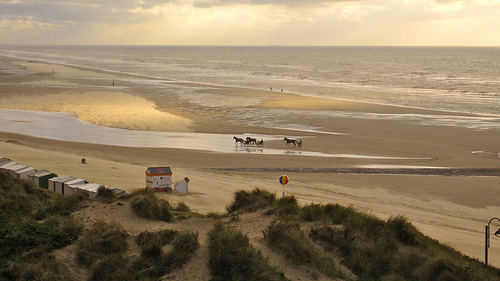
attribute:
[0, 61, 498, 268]
beach — wet, beige, golden, dry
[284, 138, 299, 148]
horse — walking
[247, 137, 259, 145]
horse — walking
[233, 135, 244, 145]
horse — walking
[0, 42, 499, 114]
water — calm, choppy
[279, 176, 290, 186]
ball — colored, red, blue, yellow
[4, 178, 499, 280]
grass — tall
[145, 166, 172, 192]
shack — small, white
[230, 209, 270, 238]
dune — grassy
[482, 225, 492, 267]
pole — metal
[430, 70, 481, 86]
wave — small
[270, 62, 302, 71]
wave — small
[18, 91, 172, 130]
sun — golden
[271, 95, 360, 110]
ray — golden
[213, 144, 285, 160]
sand — wet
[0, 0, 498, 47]
sky — cloudy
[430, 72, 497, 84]
foam — white